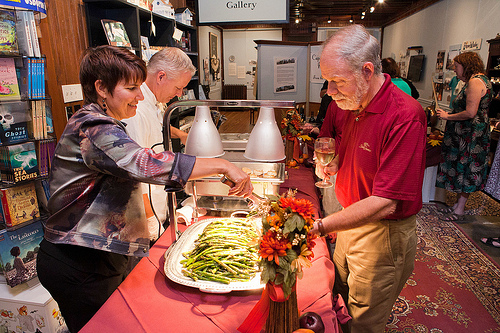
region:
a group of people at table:
[17, 16, 442, 300]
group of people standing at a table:
[50, 17, 438, 323]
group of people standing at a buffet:
[79, 7, 414, 302]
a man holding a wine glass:
[280, 23, 447, 302]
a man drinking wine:
[276, 20, 436, 302]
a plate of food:
[176, 199, 273, 304]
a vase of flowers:
[261, 175, 339, 322]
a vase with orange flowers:
[259, 177, 315, 332]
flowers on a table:
[228, 192, 322, 332]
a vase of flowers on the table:
[241, 177, 321, 327]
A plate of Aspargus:
[176, 215, 263, 302]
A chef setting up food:
[133, 43, 218, 172]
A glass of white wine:
[308, 128, 341, 193]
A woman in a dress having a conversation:
[432, 46, 499, 219]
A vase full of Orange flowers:
[253, 182, 319, 332]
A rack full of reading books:
[0, 7, 55, 309]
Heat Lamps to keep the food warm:
[183, 103, 304, 170]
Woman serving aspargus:
[39, 44, 274, 251]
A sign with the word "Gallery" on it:
[198, 0, 288, 21]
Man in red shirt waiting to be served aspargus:
[299, 32, 437, 244]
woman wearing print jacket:
[40, 24, 153, 329]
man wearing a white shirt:
[131, 38, 176, 170]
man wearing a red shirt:
[310, 19, 430, 320]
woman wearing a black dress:
[432, 43, 489, 225]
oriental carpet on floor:
[410, 226, 497, 329]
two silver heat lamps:
[152, 103, 307, 170]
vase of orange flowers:
[255, 184, 319, 329]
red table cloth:
[105, 285, 221, 332]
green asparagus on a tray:
[171, 213, 245, 297]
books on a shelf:
[8, 11, 60, 200]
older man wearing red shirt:
[281, 20, 444, 328]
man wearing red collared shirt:
[290, 17, 430, 331]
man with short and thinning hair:
[292, 19, 446, 329]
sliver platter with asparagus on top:
[159, 200, 272, 307]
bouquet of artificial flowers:
[248, 185, 320, 331]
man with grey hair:
[279, 17, 429, 330]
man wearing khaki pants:
[291, 15, 445, 328]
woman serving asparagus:
[28, 33, 258, 331]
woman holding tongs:
[35, 31, 262, 331]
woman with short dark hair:
[29, 40, 256, 327]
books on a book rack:
[3, 8, 53, 294]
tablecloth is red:
[125, 294, 232, 331]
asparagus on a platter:
[193, 217, 279, 298]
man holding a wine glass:
[313, 125, 342, 204]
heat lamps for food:
[185, 110, 316, 170]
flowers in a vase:
[242, 204, 296, 330]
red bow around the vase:
[234, 278, 294, 328]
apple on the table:
[305, 305, 339, 328]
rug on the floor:
[414, 220, 497, 310]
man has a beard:
[327, 72, 386, 115]